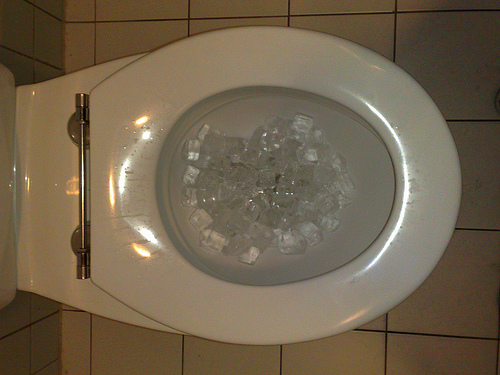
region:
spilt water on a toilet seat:
[120, 131, 144, 175]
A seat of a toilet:
[398, 108, 444, 150]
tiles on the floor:
[431, 291, 476, 340]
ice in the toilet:
[278, 183, 303, 225]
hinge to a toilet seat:
[75, 118, 91, 135]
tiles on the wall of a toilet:
[11, 333, 39, 362]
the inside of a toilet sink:
[187, 102, 364, 271]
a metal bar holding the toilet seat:
[75, 165, 87, 204]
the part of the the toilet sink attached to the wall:
[4, 70, 18, 304]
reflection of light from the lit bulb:
[109, 180, 114, 210]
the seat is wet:
[33, 42, 450, 304]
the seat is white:
[52, 28, 465, 350]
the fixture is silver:
[42, 81, 107, 278]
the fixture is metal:
[58, 68, 113, 290]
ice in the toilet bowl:
[151, 107, 377, 254]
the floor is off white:
[392, 277, 487, 356]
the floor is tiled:
[367, 295, 492, 365]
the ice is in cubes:
[140, 100, 355, 252]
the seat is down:
[64, 35, 461, 337]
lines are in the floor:
[341, 317, 490, 361]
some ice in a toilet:
[178, 112, 355, 266]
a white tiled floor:
[59, 0, 491, 372]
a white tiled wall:
[1, 0, 58, 370]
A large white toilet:
[1, 24, 464, 344]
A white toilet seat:
[86, 24, 461, 345]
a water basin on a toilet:
[0, 65, 22, 311]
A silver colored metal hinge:
[66, 90, 87, 145]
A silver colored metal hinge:
[70, 222, 91, 279]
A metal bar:
[76, 102, 88, 267]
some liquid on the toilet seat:
[101, 94, 456, 274]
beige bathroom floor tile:
[66, 345, 499, 373]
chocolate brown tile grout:
[381, 330, 390, 373]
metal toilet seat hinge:
[68, 92, 90, 282]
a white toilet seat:
[90, 25, 462, 347]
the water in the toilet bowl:
[168, 90, 383, 282]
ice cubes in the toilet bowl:
[177, 110, 357, 265]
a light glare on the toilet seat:
[106, 110, 161, 260]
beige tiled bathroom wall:
[1, 305, 58, 373]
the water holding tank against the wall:
[1, 62, 20, 310]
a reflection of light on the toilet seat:
[358, 92, 416, 279]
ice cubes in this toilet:
[12, 26, 499, 342]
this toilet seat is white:
[41, 43, 467, 363]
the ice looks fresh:
[187, 126, 374, 276]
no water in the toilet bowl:
[174, 118, 386, 250]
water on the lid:
[90, 110, 163, 290]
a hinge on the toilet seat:
[46, 84, 121, 283]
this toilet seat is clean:
[30, 52, 472, 344]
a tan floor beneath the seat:
[55, 299, 498, 372]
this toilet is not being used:
[56, 18, 470, 358]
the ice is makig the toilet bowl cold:
[77, 40, 444, 332]